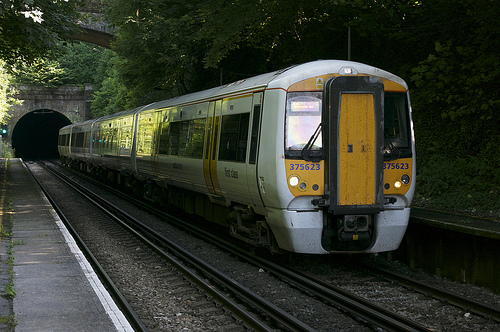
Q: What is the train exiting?
A: Tunnel.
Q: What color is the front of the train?
A: Yellow.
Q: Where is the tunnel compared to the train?
A: Behind.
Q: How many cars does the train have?
A: 4.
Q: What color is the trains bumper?
A: White.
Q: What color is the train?
A: White.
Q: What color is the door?
A: Yellow.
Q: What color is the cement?
A: Gray.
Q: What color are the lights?
A: Yellow.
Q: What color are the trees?
A: Green.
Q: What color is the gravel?
A: Gray.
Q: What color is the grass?
A: Green.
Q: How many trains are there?
A: One.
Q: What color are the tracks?
A: Black.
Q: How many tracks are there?
A: Two.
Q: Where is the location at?
A: Outside near tunnel.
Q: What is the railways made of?
A: Metal.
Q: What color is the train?
A: White and yellow.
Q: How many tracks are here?
A: Two.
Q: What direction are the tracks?
A: Parallel.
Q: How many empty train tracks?
A: One.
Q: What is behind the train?
A: Trees.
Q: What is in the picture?
A: A train.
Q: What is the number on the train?
A: 375623.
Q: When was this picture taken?
A: During the day.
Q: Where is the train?
A: On the tracks.